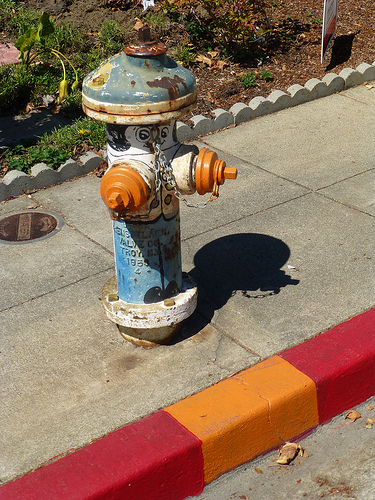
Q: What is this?
A: A fire hydrant.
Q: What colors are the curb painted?
A: Red and orange.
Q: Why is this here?
A: In case of fires.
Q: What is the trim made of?
A: Bricks.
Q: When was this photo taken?
A: During the daytime.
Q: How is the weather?
A: It's sunny.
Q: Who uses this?
A: Firemen.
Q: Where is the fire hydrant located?
A: On the sidewalk.